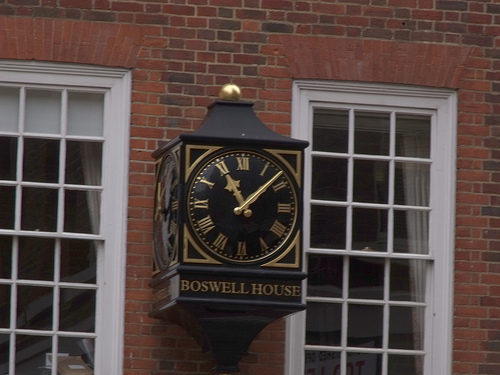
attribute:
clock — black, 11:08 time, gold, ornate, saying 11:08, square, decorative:
[146, 83, 311, 365]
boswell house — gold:
[179, 277, 303, 299]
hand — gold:
[231, 166, 284, 220]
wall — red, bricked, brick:
[2, 2, 499, 373]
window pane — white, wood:
[0, 61, 122, 374]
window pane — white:
[288, 77, 459, 372]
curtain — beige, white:
[76, 139, 107, 244]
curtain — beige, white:
[399, 130, 428, 374]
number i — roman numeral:
[258, 161, 273, 183]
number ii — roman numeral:
[273, 179, 288, 196]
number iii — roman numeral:
[276, 200, 293, 216]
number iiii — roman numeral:
[269, 219, 287, 239]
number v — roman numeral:
[258, 235, 270, 253]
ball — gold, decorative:
[220, 84, 242, 102]